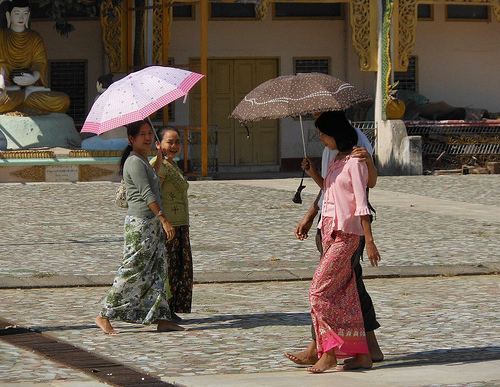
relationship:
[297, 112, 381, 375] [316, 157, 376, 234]
woman wears sweater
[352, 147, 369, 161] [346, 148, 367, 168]
hand on shoulder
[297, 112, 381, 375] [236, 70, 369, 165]
woman holds umbrella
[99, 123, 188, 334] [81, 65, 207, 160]
woman holds umbrella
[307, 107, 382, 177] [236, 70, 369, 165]
man under umbrella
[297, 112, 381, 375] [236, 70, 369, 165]
woman under umbrella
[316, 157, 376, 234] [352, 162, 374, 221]
sweater has sleeves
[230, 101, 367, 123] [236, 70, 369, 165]
ruffles on umbrella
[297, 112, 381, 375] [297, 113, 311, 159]
woman holds handle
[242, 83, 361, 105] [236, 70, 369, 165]
design on umbrella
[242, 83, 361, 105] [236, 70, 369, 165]
design circles umbrella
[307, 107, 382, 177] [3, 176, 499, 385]
man on street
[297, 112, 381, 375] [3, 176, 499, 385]
woman on street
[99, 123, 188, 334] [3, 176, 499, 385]
woman on street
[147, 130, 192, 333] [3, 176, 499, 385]
woman on street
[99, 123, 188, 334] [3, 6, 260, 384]
woman on left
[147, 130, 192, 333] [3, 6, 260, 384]
woman on left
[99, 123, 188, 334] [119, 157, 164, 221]
woman wears jacket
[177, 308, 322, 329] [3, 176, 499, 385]
shadow on street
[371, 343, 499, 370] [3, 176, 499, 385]
shadow on street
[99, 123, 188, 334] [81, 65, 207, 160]
woman under umbrella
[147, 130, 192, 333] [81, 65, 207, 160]
woman under umbrella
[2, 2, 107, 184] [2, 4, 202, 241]
statue in corner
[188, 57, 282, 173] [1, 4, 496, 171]
door in background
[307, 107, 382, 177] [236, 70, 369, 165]
man holds umbrella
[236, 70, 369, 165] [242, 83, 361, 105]
umbrella has pattern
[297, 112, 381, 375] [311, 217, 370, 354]
woman wears skirt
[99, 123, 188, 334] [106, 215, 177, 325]
woman wears skirt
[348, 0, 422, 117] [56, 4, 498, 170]
decoration on building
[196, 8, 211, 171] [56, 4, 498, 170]
pole by building